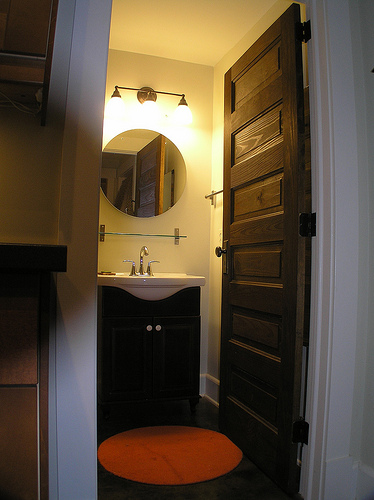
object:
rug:
[97, 424, 244, 485]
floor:
[96, 397, 294, 499]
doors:
[112, 319, 154, 400]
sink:
[115, 272, 184, 279]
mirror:
[100, 128, 187, 218]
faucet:
[139, 245, 149, 275]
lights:
[106, 85, 129, 122]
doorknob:
[214, 245, 226, 257]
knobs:
[145, 324, 153, 332]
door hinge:
[299, 211, 316, 237]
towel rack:
[203, 190, 223, 208]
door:
[215, 2, 306, 495]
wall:
[97, 49, 214, 271]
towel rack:
[99, 225, 187, 244]